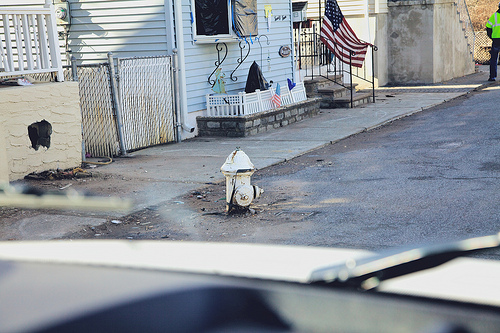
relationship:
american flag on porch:
[305, 7, 370, 83] [295, 27, 350, 100]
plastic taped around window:
[197, 1, 225, 31] [189, 0, 232, 42]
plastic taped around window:
[236, 3, 256, 35] [232, 3, 260, 39]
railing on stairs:
[293, 17, 379, 108] [304, 61, 383, 107]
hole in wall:
[36, 105, 96, 160] [30, 11, 370, 166]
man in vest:
[482, 2, 499, 85] [486, 11, 499, 43]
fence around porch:
[0, 0, 65, 82] [0, 13, 75, 89]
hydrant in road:
[209, 140, 297, 241] [63, 85, 487, 323]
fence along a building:
[68, 53, 162, 154] [0, 15, 297, 157]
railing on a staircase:
[293, 17, 379, 108] [313, 67, 377, 112]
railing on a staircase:
[350, 34, 372, 77] [313, 67, 377, 112]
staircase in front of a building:
[303, 21, 386, 122] [67, 2, 299, 148]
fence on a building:
[0, 0, 65, 82] [1, 2, 373, 139]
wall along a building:
[46, 17, 494, 143] [382, 0, 498, 136]